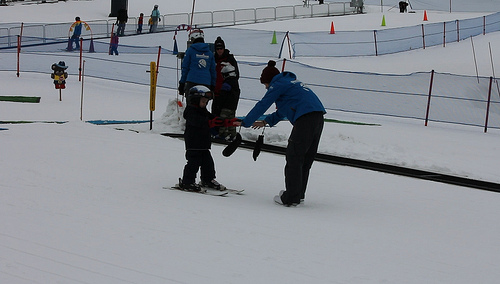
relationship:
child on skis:
[171, 84, 229, 189] [164, 174, 247, 201]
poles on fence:
[417, 68, 494, 131] [436, 72, 484, 125]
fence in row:
[436, 72, 484, 125] [331, 70, 499, 133]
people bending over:
[233, 60, 328, 207] [242, 57, 330, 130]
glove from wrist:
[221, 132, 250, 154] [233, 119, 249, 129]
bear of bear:
[51, 61, 70, 90] [49, 60, 71, 90]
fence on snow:
[436, 72, 484, 125] [415, 120, 497, 151]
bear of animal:
[51, 61, 70, 90] [49, 60, 71, 90]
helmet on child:
[188, 84, 216, 108] [171, 84, 229, 189]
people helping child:
[233, 60, 328, 207] [171, 84, 229, 189]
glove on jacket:
[221, 132, 250, 154] [242, 57, 330, 130]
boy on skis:
[171, 84, 229, 189] [164, 174, 247, 201]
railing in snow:
[321, 151, 498, 198] [415, 120, 497, 151]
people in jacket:
[233, 60, 328, 207] [242, 57, 330, 130]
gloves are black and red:
[208, 115, 242, 129] [214, 122, 228, 124]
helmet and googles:
[188, 84, 216, 108] [200, 91, 214, 98]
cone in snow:
[267, 27, 284, 46] [415, 120, 497, 151]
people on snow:
[114, 6, 171, 39] [415, 120, 497, 151]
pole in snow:
[419, 68, 435, 127] [415, 120, 497, 151]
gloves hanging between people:
[208, 115, 242, 129] [171, 60, 343, 207]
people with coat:
[233, 60, 328, 207] [242, 57, 330, 130]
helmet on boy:
[188, 84, 216, 108] [171, 84, 229, 189]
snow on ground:
[415, 120, 497, 151] [6, 160, 497, 283]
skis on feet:
[164, 174, 247, 201] [180, 174, 227, 191]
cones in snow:
[259, 10, 440, 45] [415, 120, 497, 151]